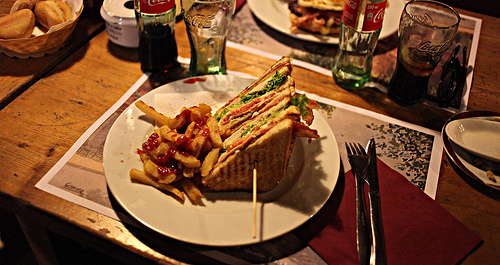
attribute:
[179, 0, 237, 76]
glass — empty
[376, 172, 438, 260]
napkin — red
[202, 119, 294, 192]
bread — white, toasted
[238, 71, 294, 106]
lettuce — healthy, green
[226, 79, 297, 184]
sandwich — grilled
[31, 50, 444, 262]
mat — paper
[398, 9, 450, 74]
glass — half empty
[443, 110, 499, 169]
plate — empty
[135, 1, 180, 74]
bottle — half full, empty, Coke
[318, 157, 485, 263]
napkin — maroon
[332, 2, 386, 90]
bottle — empty, Coke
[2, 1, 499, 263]
table — brown, scarred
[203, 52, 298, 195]
sandwich — sliced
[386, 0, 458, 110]
cup — clear